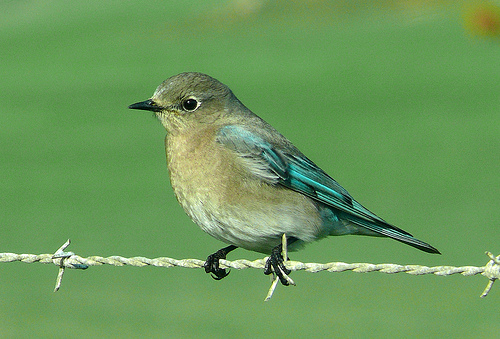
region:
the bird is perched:
[67, 32, 442, 312]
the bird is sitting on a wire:
[76, 23, 428, 296]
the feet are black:
[175, 217, 307, 297]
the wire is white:
[12, 215, 477, 312]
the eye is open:
[175, 77, 209, 121]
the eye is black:
[162, 85, 213, 120]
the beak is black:
[120, 88, 165, 118]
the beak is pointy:
[113, 92, 159, 120]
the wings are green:
[202, 101, 439, 267]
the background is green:
[45, 4, 460, 302]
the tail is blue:
[288, 164, 426, 258]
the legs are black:
[204, 251, 308, 286]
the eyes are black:
[175, 90, 207, 112]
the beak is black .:
[127, 93, 167, 117]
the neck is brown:
[163, 146, 225, 195]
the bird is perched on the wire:
[132, 50, 460, 310]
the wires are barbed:
[52, 245, 156, 284]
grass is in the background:
[381, 54, 456, 180]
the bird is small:
[145, 69, 452, 290]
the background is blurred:
[303, 40, 498, 182]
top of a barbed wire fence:
[0, 241, 498, 298]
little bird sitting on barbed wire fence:
[130, 65, 439, 284]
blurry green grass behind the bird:
[2, 4, 492, 336]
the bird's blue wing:
[230, 130, 392, 227]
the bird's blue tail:
[324, 213, 440, 253]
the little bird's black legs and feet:
[205, 244, 291, 286]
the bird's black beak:
[127, 99, 163, 111]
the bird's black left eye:
[182, 98, 197, 110]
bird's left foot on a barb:
[266, 238, 293, 286]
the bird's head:
[127, 68, 239, 127]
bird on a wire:
[128, 65, 445, 282]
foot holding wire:
[203, 244, 234, 284]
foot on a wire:
[261, 247, 301, 282]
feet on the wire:
[200, 237, 298, 290]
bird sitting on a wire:
[126, 61, 443, 268]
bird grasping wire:
[128, 70, 444, 282]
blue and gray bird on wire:
[126, 65, 440, 266]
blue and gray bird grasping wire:
[128, 67, 444, 277]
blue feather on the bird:
[224, 123, 447, 259]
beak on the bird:
[126, 98, 163, 112]